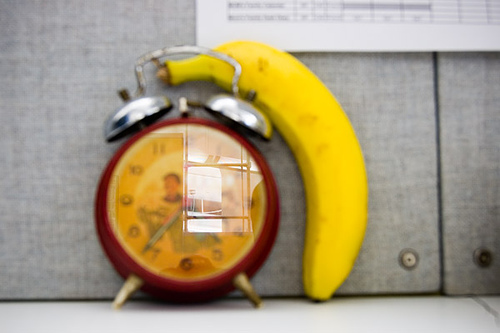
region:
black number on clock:
[178, 251, 198, 274]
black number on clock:
[203, 240, 230, 261]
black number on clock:
[229, 225, 254, 250]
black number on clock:
[236, 189, 260, 211]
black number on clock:
[125, 219, 147, 251]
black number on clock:
[118, 195, 137, 209]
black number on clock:
[123, 161, 143, 183]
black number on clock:
[149, 135, 170, 159]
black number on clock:
[210, 142, 230, 158]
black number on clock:
[234, 156, 250, 181]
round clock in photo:
[64, 100, 293, 280]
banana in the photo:
[173, 33, 416, 317]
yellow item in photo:
[280, 83, 374, 215]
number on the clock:
[121, 148, 153, 183]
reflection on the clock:
[168, 138, 264, 233]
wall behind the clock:
[9, 67, 90, 156]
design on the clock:
[146, 163, 189, 212]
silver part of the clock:
[90, 56, 272, 141]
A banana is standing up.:
[156, 39, 368, 304]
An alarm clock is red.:
[91, 45, 273, 310]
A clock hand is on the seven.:
[136, 205, 181, 260]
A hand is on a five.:
[185, 205, 227, 260]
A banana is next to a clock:
[93, 38, 370, 319]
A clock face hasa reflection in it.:
[106, 122, 268, 284]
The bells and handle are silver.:
[103, 42, 274, 145]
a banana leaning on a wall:
[178, 50, 368, 297]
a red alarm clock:
[111, 103, 271, 283]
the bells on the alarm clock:
[88, 68, 279, 153]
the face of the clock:
[118, 135, 255, 275]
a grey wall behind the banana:
[370, 53, 492, 261]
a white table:
[12, 302, 498, 328]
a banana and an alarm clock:
[106, 40, 382, 275]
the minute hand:
[148, 213, 198, 253]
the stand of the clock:
[233, 277, 272, 315]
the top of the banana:
[159, 50, 222, 81]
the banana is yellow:
[155, 36, 367, 301]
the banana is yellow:
[155, 34, 384, 317]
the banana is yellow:
[144, 31, 363, 298]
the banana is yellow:
[146, 25, 356, 332]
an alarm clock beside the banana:
[72, 23, 379, 330]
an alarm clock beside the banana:
[64, 14, 369, 314]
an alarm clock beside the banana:
[51, 23, 390, 306]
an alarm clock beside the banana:
[47, 25, 378, 328]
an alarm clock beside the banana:
[57, 24, 375, 329]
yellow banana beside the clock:
[160, 22, 381, 305]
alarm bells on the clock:
[101, 72, 270, 149]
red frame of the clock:
[89, 114, 276, 292]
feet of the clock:
[105, 260, 272, 318]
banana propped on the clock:
[153, 41, 362, 298]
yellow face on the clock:
[110, 130, 271, 284]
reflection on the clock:
[178, 128, 258, 236]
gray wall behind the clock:
[2, 2, 499, 290]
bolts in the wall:
[392, 240, 493, 275]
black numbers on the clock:
[116, 132, 263, 273]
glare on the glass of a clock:
[176, 128, 253, 236]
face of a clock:
[104, 123, 267, 283]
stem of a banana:
[147, 48, 211, 95]